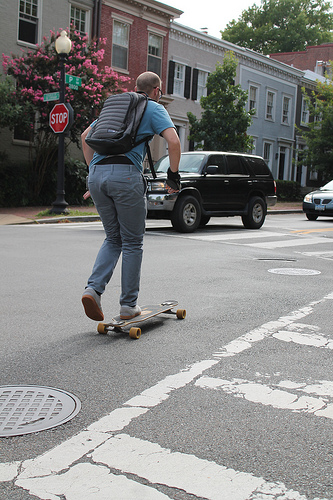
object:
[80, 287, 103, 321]
shoe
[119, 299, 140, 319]
shoe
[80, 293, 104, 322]
soles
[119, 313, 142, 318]
soles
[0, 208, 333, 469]
ground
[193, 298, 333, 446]
cracked line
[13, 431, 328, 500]
white line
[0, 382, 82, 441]
manhole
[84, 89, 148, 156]
backpack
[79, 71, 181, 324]
man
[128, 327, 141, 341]
wheel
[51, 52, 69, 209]
pole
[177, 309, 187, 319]
wheel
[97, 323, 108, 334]
wheel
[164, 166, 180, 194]
hand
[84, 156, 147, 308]
blue jeans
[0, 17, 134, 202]
tree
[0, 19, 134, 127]
flowers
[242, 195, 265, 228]
tire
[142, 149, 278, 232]
car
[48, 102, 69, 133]
sign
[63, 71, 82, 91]
sign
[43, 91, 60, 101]
sign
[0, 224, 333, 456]
road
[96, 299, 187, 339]
skateboard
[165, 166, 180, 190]
glove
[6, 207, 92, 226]
corner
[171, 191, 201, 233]
tire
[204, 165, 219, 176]
mirror